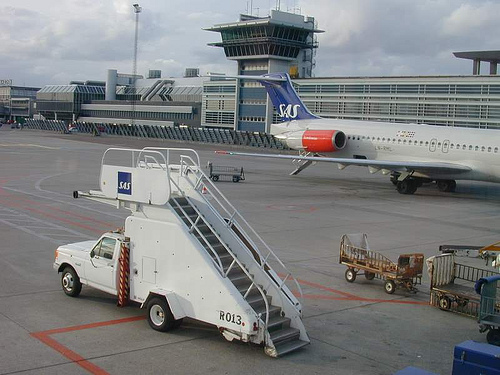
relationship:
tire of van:
[145, 296, 182, 331] [51, 145, 313, 357]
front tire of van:
[62, 266, 82, 297] [51, 145, 313, 357]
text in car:
[114, 179, 131, 194] [52, 147, 311, 359]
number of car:
[219, 309, 241, 330] [52, 147, 311, 359]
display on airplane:
[275, 100, 299, 120] [198, 70, 499, 195]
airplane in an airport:
[202, 52, 498, 188] [23, 7, 483, 208]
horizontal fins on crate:
[213, 71, 298, 92] [258, 72, 322, 124]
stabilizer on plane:
[254, 37, 329, 116] [212, 41, 500, 184]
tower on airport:
[219, 7, 331, 89] [52, 4, 483, 298]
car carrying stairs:
[54, 214, 259, 345] [114, 145, 311, 357]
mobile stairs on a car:
[72, 146, 310, 359] [52, 147, 311, 359]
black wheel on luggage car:
[436, 294, 450, 310] [426, 250, 497, 313]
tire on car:
[145, 296, 182, 331] [28, 204, 212, 334]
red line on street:
[34, 309, 156, 374] [4, 123, 497, 373]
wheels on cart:
[61, 276, 175, 336] [330, 208, 430, 300]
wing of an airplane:
[211, 145, 476, 178] [196, 72, 499, 194]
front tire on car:
[61, 271, 80, 295] [52, 147, 311, 359]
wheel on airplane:
[438, 178, 450, 192] [196, 72, 499, 194]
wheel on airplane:
[396, 179, 410, 194] [196, 72, 499, 194]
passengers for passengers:
[341, 131, 500, 159] [341, 131, 499, 159]